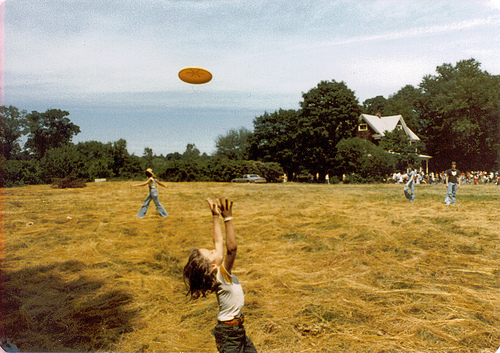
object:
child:
[183, 198, 257, 353]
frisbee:
[177, 67, 213, 85]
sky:
[1, 1, 499, 157]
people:
[130, 168, 172, 220]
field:
[0, 179, 499, 352]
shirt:
[212, 261, 246, 321]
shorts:
[211, 316, 255, 352]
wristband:
[223, 216, 232, 222]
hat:
[145, 168, 155, 178]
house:
[353, 112, 432, 175]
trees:
[247, 78, 365, 183]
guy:
[402, 167, 417, 201]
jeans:
[403, 179, 415, 200]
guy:
[444, 161, 462, 205]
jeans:
[443, 181, 460, 204]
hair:
[181, 247, 220, 302]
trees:
[330, 135, 404, 184]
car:
[231, 173, 266, 183]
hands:
[204, 196, 224, 214]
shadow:
[0, 258, 145, 351]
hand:
[131, 185, 136, 189]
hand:
[165, 184, 169, 187]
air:
[225, 217, 237, 274]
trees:
[360, 58, 499, 172]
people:
[398, 169, 408, 184]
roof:
[358, 113, 421, 141]